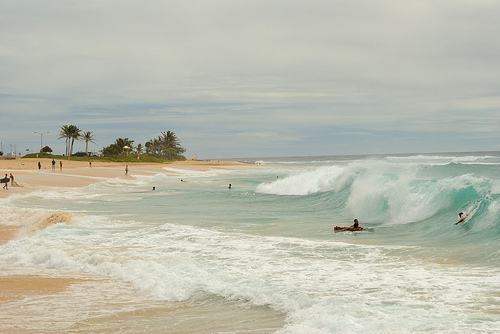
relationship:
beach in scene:
[0, 153, 497, 332] [11, 0, 496, 328]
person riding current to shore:
[457, 211, 463, 219] [1, 203, 498, 329]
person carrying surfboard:
[2, 173, 8, 191] [2, 175, 12, 183]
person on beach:
[2, 173, 8, 191] [2, 147, 497, 332]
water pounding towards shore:
[284, 151, 474, 248] [6, 153, 219, 332]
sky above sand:
[12, 19, 263, 148] [4, 160, 177, 330]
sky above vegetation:
[12, 19, 263, 148] [31, 124, 189, 160]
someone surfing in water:
[349, 214, 361, 231] [0, 145, 499, 331]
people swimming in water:
[35, 156, 242, 195] [37, 161, 499, 330]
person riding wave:
[457, 211, 463, 219] [255, 153, 498, 228]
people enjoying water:
[152, 185, 156, 189] [0, 145, 499, 331]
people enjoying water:
[181, 179, 187, 183] [0, 145, 499, 331]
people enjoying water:
[226, 183, 232, 188] [0, 145, 499, 331]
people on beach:
[32, 158, 129, 180] [8, 146, 235, 312]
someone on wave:
[350, 218, 360, 231] [325, 163, 434, 217]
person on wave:
[457, 211, 463, 219] [325, 163, 434, 217]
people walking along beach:
[28, 150, 131, 182] [3, 153, 255, 332]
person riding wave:
[454, 205, 466, 220] [254, 162, 499, 244]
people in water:
[152, 185, 156, 189] [0, 145, 499, 331]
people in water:
[180, 178, 187, 183] [0, 145, 499, 331]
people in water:
[228, 183, 232, 189] [0, 145, 499, 331]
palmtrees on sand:
[57, 120, 97, 166] [0, 157, 177, 330]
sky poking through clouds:
[257, 62, 399, 143] [1, 2, 498, 148]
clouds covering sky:
[1, 2, 498, 148] [1, 2, 498, 160]